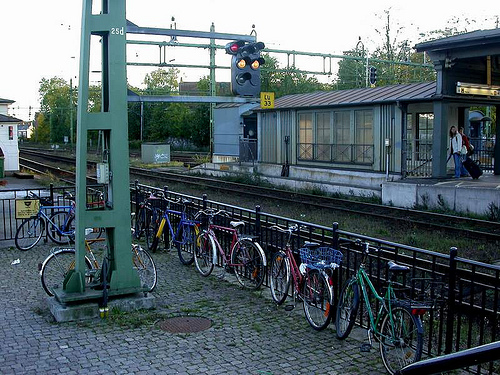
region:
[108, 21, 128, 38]
"25d" on green metal structure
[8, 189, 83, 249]
blue bike in background behind green metal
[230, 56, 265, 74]
two yellow traffic lights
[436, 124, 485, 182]
person on platform in far right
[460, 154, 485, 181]
roller suitcase held by person on far right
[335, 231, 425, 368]
green bike at end of row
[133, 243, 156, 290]
front tire of yellow bike parked directly behind green structure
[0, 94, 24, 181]
part of white building at top left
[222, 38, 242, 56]
single red traffic light over two yellow ones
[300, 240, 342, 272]
blue basket on red bike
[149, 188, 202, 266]
a blue and yellow bicycle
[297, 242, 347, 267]
a blue basket on a bicycle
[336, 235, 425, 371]
a green bicycle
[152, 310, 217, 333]
a manhole cover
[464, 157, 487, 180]
a black suitcase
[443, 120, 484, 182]
a woman waiting at a train station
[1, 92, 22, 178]
a white house next to the tracks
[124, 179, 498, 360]
black railing next to the tracks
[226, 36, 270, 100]
a signal light above the train tracks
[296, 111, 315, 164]
a window at the train station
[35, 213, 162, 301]
a bicycle parked on a steel beam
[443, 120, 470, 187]
person wearing a white jacket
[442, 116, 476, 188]
person wearing blue jeans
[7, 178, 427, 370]
bunch of bicycles parked down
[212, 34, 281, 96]
a railroad traffic signal light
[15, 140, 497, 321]
two lane of railroad rails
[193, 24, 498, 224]
a train station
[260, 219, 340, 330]
a pink bicycle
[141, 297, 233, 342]
a steel manhole on the platform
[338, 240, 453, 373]
This is a bicycle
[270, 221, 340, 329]
This is a bicycle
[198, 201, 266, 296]
This is a bicycle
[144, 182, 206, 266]
This is a bicycle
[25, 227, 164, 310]
This is a bicycle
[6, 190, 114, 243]
This is a bicycle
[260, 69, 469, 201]
This is a house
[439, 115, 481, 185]
This is a person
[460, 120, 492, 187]
This is a person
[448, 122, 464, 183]
This is a person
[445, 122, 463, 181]
A woman in white waiting on the platform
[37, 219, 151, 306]
A yellow bike against a green metal structure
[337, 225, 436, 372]
A green bike linked to a black metal fence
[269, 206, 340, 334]
A red bike with a blue rear basket against a black metal fence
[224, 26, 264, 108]
A traffic light for the trains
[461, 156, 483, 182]
The black luggage belonging to the woman in white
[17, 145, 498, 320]
Two sets of train tracks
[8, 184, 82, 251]
The blue bike on the far section of black fencing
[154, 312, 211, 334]
A man hole cover by the bikes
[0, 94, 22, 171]
A white home or building at the left edge of photo